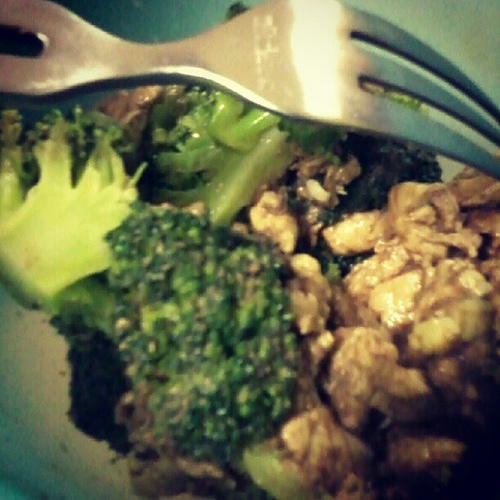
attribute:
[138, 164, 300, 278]
food — close up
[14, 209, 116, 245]
broccoli — stalk, cooked, green, cut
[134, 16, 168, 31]
bowl — here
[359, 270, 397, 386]
chicken — pieces, piece, brown, browny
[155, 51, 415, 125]
fork — silver, design, pronged, big, upside down, shiny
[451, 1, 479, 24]
wall — white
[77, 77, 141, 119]
onion — cooked